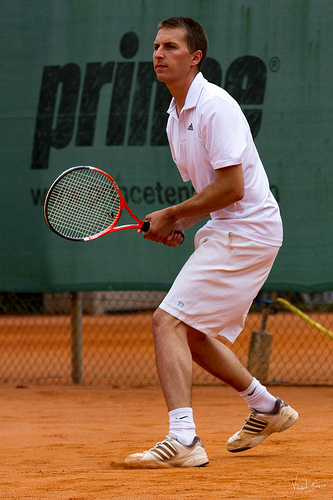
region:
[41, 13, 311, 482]
Man is playing tennis.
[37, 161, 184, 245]
Orange and black racquet.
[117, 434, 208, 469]
white shoe on foot.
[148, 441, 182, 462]
Black stripes on the shoe.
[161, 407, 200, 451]
White sock on the foot.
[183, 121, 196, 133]
Logo on the shirt.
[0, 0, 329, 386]
Fence in the background.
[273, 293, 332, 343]
yellow bar in the background.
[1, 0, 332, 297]
Green cover on the fence.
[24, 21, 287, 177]
black letters on the cover.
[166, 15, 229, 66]
man has brown hair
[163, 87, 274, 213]
man has white shirt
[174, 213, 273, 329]
man has white shorts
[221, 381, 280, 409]
black and white socks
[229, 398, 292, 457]
white and brown shoes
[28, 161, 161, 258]
red and black racket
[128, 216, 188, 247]
black grip on racket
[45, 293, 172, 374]
brown posts on fence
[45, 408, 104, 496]
playing surface is orange clay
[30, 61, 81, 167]
black letter on wall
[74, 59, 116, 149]
black letter on wall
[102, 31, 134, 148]
black letter on wall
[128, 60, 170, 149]
black letter on wall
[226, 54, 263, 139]
black letter on wall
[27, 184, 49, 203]
black letter on wall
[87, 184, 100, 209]
black letter on wall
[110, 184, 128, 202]
black letter on wall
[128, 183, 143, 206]
black letter on wall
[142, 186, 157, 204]
black letter on wall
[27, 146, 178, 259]
a red and black tennis racket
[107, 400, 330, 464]
white tennis shoes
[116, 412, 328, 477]
the shoes are Adidas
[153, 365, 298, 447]
the socks are Nike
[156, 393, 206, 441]
white Nike socks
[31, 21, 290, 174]
this says PRINCE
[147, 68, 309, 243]
he is wearing a white shirt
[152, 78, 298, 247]
a white tennis shirt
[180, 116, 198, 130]
this is a black Adidas logo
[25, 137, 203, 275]
this is a tennis racket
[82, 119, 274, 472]
man is playing tennis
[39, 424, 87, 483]
sand on the ground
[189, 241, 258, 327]
shorts on the man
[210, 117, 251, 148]
the shirt is white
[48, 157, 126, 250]
netting on the racket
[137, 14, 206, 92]
head of the man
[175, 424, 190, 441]
the socks are white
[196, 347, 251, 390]
leg of the man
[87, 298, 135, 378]
netting on the fence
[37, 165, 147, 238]
red and black tennis racket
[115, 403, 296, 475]
white and black tennis shoes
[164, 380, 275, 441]
white socks with black nike swoosh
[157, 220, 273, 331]
white shorts the man is wearing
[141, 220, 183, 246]
black handle of the tennis racket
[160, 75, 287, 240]
white shirt the man is wearing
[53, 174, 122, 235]
white strings on the racket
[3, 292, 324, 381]
chain link fence behind the man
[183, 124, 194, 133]
black logo on the white shirt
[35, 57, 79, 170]
A letter on a sign.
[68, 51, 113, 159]
A letter on a sign.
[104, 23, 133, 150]
A letter on a sign.